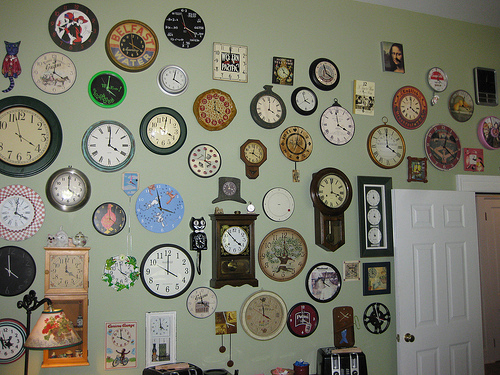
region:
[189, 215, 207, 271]
a black cat clock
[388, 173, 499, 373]
an open white door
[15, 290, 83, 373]
a black lamp with a floral shade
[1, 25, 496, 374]
a wall of clocks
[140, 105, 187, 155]
a round clock with a green ring around it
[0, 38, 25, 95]
a gray cat with a red shirt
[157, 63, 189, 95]
a clock with a silver trim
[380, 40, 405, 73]
a picture of the Mona Lisa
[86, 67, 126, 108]
a clock with a green rim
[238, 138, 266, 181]
a brown wood trimmed clock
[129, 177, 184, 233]
A round, blue clock.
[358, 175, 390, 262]
Three clocks in a rectangular frame.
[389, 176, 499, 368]
an open white door.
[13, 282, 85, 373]
A antique lamp.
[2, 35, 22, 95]
A clock in the shape of a cat.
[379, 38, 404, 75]
A picture of Mona Lisa.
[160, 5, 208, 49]
A round, black and white clock.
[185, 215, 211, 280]
A clock in the shape of a black cat.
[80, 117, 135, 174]
A clock that uses roman numerals.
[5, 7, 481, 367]
A wall full of an assortment of different kinds of clocks.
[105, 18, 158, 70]
Small clock with words on it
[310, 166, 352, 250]
A brown clock on a wall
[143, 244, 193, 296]
A black circle clock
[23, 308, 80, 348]
A flower lamp shade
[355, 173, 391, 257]
Three clocks in one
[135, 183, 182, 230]
A blue clock on a wall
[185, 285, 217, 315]
A tiny clock on a wall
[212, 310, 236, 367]
A squared clock on a wall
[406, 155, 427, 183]
A square that has clock hands on it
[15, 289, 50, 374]
A black lamp stand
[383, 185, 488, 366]
door that is ajar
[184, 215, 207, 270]
cat clock on wall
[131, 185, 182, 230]
blue clock on wall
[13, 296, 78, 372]
lamp near the clocks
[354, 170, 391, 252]
column of clocks on wall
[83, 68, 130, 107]
clocked lined in bright green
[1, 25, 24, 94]
blue cat clock on wall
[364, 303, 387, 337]
clock with outline on wall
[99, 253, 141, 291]
clock lined with plants on wall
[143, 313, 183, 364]
rectangular clock on wall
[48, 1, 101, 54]
round wall clock with a black and red design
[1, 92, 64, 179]
round clock with a black frame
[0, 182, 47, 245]
round clock with a red and white frame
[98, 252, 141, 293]
small white clock with a green design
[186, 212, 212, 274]
black and white cat clock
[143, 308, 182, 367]
white rectangular clock on a wall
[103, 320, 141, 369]
curious george clock on a wall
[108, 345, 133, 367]
curious george on a bicycle graphic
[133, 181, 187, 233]
round blue clock on a wall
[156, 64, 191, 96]
small clock with a silver frame on it